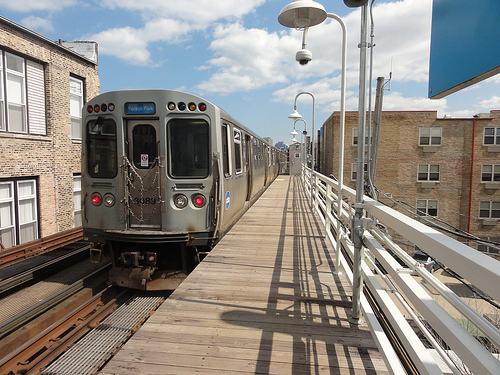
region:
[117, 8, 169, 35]
white clouds in blue sky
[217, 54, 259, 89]
white clouds in blue sky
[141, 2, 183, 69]
white clouds in blue sky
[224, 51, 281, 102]
white clouds in blue sky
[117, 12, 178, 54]
white clouds in blue sky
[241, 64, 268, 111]
white clouds in blue sky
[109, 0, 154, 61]
white clouds in blue sky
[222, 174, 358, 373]
shadow of lights on ground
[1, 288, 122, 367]
train tracks on the ground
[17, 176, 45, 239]
window on the building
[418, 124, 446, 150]
windows on the house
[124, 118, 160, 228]
back door of the train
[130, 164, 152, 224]
chains on back door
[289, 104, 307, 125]
street light on pole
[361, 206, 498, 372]
white barrier around tracks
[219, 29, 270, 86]
clouds in the sky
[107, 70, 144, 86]
patch of clear blue sky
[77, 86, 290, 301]
Train on the tracks.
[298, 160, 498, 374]
White railing on the platform.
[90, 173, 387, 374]
Wooden platform by the train.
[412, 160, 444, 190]
Window on the building.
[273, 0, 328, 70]
Lights over the platform.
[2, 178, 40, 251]
White curtains in the window.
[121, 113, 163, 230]
Door on the train.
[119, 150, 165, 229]
chains on the door.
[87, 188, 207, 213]
Lights on the train.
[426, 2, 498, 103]
Blue sign on the platform.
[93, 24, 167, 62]
white clouds in blue sky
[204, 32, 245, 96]
white clouds in blue sky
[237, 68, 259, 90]
white clouds in blue sky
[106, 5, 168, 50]
white clouds in blue sky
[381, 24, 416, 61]
white clouds in blue sky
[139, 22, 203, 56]
white clouds in blue sky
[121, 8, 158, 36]
white clouds in blue sky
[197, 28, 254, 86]
white clouds in blue sky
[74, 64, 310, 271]
A silver train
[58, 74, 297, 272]
A silver train on the tracks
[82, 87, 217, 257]
A silver train with red headlights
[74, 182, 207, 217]
four train headlights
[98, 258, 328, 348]
wooden platform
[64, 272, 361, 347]
wooden platform next to railway tracks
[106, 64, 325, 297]
wooden platform next to a silver train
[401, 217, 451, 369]
white fence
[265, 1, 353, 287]
A light on a wooden platform